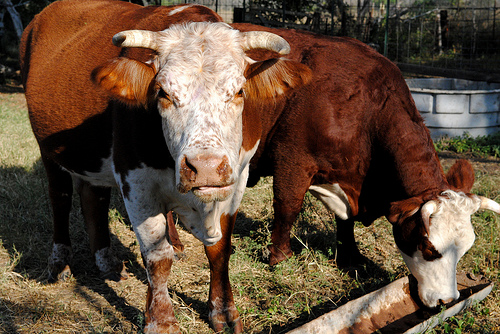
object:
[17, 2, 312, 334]
cow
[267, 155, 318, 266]
leg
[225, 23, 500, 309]
cow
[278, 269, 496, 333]
trough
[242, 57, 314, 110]
ear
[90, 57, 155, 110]
ear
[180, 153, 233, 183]
nose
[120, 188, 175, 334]
leg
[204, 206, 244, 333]
leg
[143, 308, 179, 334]
hooves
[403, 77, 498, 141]
container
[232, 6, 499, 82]
fence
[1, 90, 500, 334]
grass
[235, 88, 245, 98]
eyes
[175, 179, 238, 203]
mouth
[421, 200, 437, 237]
horn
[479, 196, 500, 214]
horn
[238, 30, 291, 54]
horn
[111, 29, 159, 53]
horn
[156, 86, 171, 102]
eye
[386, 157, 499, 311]
head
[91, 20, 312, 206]
head